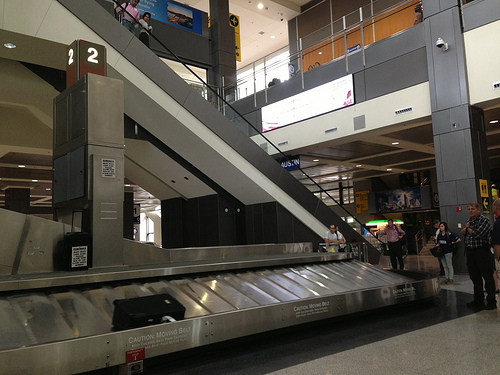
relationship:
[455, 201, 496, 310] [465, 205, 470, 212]
man has eye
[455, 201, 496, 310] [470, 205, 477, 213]
man has eye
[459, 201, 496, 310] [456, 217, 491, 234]
man has arm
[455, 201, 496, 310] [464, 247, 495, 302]
man has legs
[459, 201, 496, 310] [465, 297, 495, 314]
man has foot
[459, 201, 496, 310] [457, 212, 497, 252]
man wears shirt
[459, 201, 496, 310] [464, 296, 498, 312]
man wears shoes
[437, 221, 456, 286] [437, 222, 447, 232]
woman has head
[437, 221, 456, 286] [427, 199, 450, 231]
woman has hair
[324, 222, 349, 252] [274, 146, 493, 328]
people on stairs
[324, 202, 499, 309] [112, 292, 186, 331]
people wait luggage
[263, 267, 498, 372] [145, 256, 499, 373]
tile on floor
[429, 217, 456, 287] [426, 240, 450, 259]
woman carry bag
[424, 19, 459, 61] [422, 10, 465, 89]
camera on wall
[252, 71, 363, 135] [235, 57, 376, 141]
sign on wall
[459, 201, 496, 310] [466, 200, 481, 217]
man has head